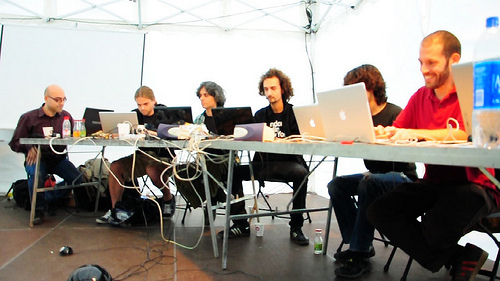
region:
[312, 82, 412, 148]
the white color laptop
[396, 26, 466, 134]
the man with red colored t shirt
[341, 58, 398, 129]
a man with green colored t shirt sitting in front of laptop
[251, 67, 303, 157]
a man in black color t shirt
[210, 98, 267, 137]
the black color laptop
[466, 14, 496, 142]
the water bottle with blue color sticker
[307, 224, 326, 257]
the bottle with green color sticker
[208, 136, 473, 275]
the steel table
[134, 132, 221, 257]
the bunch of wires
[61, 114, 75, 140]
the small bottle with red color cap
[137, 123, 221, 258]
wiring from electronic on table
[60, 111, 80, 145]
white drink bottle with red lid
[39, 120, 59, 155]
snall white styrofoam cup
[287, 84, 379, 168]
two white laptops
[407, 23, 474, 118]
man smiling behind computer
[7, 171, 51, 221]
black canvas bag on floor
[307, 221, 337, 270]
drink bottle sitting on floor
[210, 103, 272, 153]
black of black laptop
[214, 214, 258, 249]
mens black shoes with white stripes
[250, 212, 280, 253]
white cup with red design on floor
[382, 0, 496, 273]
Man wearing a red shirt.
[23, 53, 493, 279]
Men on laptops on tables.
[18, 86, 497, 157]
Seven laptops on tables.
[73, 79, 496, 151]
Four silver laptops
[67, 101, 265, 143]
Three black laptops.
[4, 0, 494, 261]
People are inside a tent.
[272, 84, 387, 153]
Two MAC computers on the right.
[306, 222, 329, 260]
Empty bottle of juice on the floor.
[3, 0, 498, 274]
No women pictured.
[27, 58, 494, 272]
Six men pictured.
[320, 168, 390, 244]
blue jeans under table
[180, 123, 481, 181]
white table with electronics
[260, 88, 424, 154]
two mac's beside eachother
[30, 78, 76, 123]
bald man with glasses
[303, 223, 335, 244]
water bottle on florr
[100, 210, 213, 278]
cords on floor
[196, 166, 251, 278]
white leg of table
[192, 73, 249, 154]
dark hair of person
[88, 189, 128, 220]
white and black shoe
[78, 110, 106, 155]
black computer on table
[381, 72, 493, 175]
a red collared shirt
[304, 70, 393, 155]
a white apple laptop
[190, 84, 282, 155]
a small black laptop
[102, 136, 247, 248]
a jumble of white cables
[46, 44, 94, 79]
a section of wall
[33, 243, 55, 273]
the brown tiled floor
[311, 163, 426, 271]
these are blue jeans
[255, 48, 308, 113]
long brown curly hair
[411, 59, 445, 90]
a bright white smile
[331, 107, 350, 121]
the white apple logo